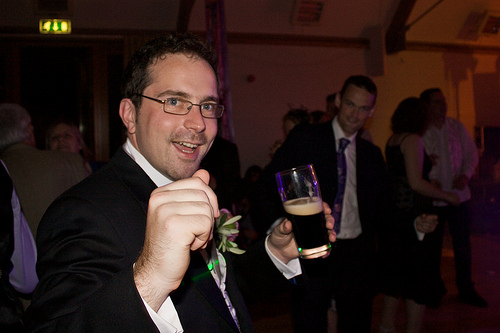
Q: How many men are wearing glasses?
A: One.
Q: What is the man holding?
A: Beer.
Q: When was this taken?
A: At a party.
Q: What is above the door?
A: A green and white sign.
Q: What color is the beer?
A: Brown.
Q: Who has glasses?
A: The man with the beer.